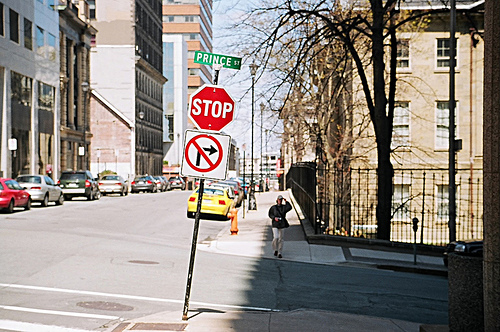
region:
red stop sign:
[187, 82, 239, 132]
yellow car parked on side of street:
[184, 187, 236, 221]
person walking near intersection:
[266, 192, 294, 261]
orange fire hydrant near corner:
[226, 207, 240, 234]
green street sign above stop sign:
[191, 48, 244, 71]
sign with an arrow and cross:
[179, 126, 231, 183]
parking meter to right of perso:
[407, 214, 420, 263]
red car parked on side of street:
[0, 175, 31, 212]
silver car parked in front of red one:
[13, 172, 65, 206]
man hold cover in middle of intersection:
[128, 255, 159, 267]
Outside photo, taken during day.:
[9, 1, 499, 328]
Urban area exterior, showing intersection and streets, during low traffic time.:
[1, 3, 495, 328]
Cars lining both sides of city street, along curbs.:
[7, 150, 318, 265]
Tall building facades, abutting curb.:
[7, 1, 228, 173]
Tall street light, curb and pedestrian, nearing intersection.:
[243, 66, 298, 262]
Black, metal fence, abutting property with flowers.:
[288, 162, 461, 246]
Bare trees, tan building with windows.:
[278, 1, 479, 226]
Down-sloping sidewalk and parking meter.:
[296, 208, 448, 282]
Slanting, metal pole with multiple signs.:
[179, 26, 242, 325]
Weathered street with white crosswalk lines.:
[16, 219, 191, 331]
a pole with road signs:
[172, 40, 250, 328]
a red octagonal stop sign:
[183, 75, 242, 135]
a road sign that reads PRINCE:
[188, 45, 250, 74]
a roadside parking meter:
[404, 212, 429, 267]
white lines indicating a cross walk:
[0, 278, 285, 330]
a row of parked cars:
[0, 163, 187, 205]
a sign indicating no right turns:
[182, 129, 231, 189]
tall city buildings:
[2, 0, 203, 174]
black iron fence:
[282, 158, 367, 239]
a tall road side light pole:
[244, 48, 274, 218]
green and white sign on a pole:
[184, 43, 251, 81]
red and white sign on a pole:
[178, 75, 240, 136]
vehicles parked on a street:
[0, 166, 129, 225]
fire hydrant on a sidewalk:
[222, 203, 247, 242]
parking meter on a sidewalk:
[404, 210, 429, 276]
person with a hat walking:
[262, 189, 299, 262]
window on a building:
[428, 32, 466, 85]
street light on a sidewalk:
[240, 53, 265, 213]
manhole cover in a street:
[117, 248, 170, 275]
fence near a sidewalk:
[282, 155, 321, 242]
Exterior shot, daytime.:
[4, 5, 488, 331]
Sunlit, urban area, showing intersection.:
[5, 5, 475, 324]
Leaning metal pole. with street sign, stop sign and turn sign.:
[183, 37, 243, 320]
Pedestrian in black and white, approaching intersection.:
[269, 192, 296, 257]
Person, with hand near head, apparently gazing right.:
[271, 190, 297, 215]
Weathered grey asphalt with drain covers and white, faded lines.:
[18, 205, 175, 330]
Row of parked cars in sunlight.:
[0, 167, 205, 204]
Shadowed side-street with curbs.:
[237, 226, 469, 331]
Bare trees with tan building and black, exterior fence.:
[305, 13, 492, 245]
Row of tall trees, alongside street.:
[10, 5, 210, 194]